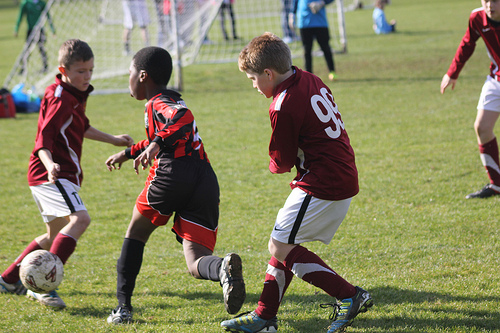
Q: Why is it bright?
A: Sun.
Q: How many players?
A: 4.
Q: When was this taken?
A: Daytime.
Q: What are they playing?
A: Soccer.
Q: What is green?
A: Grass.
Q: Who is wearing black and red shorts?
A: Boy in middle.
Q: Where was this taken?
A: At a soccer game.